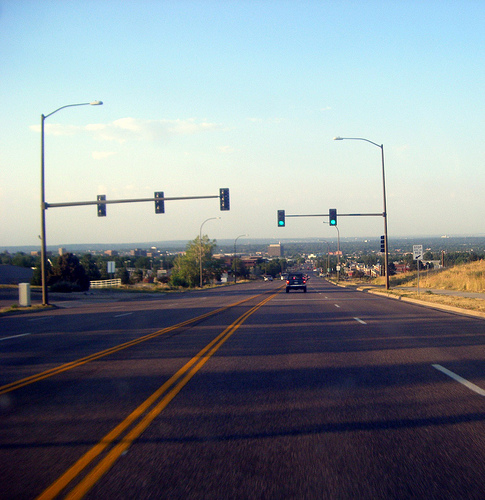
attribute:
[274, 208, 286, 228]
streetlight — green, lit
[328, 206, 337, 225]
streetlight — green, lit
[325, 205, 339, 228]
street light — green, on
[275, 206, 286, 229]
street light — green, on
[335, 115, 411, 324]
pole — gray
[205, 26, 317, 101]
sky — blue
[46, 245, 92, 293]
bush — dark green, big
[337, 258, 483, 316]
grass — light brown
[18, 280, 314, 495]
stripes — yellow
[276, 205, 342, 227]
light — green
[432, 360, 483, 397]
stripes — white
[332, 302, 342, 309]
stripes — white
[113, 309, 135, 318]
stripes — white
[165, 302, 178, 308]
stripes — white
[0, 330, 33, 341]
stripes — white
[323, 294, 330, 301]
stripes — white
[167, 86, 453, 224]
clouds — white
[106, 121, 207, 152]
clouds — white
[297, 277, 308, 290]
light — red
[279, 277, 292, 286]
light — red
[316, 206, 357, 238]
light — red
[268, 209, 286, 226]
light — red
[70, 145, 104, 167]
clouds — white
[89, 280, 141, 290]
fence — white, thin, long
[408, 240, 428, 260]
street sign — black, white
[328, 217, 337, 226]
signal light — green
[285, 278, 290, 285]
taillight — lit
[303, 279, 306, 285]
taillight — lit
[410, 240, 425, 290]
street sign — black, white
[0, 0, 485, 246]
sky — blue